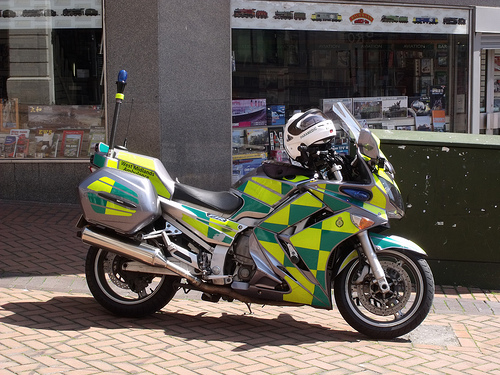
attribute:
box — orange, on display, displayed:
[430, 108, 446, 131]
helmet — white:
[280, 110, 338, 161]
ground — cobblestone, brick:
[0, 196, 499, 374]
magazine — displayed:
[232, 101, 273, 131]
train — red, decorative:
[228, 6, 270, 22]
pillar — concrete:
[97, 3, 235, 200]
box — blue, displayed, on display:
[270, 103, 287, 130]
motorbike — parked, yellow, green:
[80, 66, 440, 340]